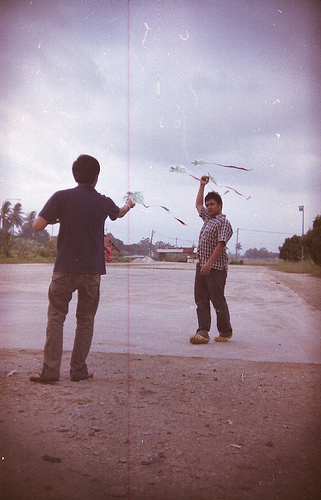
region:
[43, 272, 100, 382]
a grey pair of pants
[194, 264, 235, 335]
a blue pair of jeans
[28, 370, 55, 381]
a man's sandal shoe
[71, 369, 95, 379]
a man's sandal shoe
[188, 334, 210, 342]
a man's sandal shoe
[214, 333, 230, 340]
a man's sandal shoe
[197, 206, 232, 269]
a black and white checkered shirt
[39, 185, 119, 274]
a dark blue shirt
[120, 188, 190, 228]
a white kite with red tail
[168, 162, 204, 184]
a white kite with red tail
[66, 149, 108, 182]
head of a person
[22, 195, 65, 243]
arm of a person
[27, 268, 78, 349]
leg of a person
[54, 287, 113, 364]
leg of a person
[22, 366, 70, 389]
feet of a person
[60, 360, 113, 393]
feet of a person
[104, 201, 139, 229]
arm of a person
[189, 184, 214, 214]
arm of a person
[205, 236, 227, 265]
arm of a person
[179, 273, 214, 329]
leg of a person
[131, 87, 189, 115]
the sky is blue in color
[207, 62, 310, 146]
the sky has clouds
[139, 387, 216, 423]
this is the ground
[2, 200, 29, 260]
these are some trees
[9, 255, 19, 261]
the leaves are green in color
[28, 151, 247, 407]
these are two people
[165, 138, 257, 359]
man holding the kites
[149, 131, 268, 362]
man holding the kites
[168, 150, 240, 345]
man holding the kites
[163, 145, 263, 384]
man holding the kites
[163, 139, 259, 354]
man holding the kites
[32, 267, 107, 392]
the pants are brown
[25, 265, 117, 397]
the pants are brown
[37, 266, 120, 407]
the pants are brown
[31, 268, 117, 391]
the pants are brown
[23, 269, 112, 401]
the pants are brown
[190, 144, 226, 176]
a kite in the air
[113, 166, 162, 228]
a kite in the air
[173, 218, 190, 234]
a kite in the air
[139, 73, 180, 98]
a kite in the air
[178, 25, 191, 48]
a kite in the air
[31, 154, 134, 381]
the man is standing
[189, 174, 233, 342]
the man is standing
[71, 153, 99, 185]
the hair is black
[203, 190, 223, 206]
the hair is black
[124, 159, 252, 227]
the kites are flying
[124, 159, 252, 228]
the kites are in the air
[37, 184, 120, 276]
the shirt is dark colored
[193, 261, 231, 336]
the pants are black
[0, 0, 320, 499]
the sky above the dirt on the ground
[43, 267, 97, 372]
jeans on a man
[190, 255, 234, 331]
blue pair of jeans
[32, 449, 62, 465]
debris on the ground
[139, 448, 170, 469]
debris on the ground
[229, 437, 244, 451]
debris on the ground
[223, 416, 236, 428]
debris on the ground